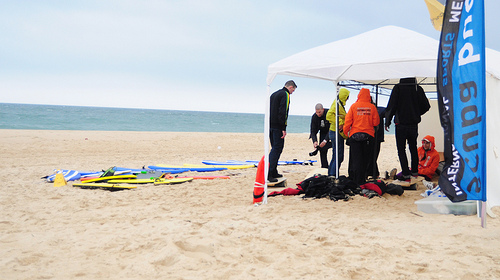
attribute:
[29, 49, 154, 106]
clouds — white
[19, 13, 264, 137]
sky — blue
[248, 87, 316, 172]
man —   in black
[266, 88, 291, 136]
shirt — black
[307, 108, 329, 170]
wetsuit — black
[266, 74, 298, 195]
wetsuit — black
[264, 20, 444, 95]
canopy — white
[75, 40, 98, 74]
clouds — white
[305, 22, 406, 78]
tent — white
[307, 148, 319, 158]
socks — black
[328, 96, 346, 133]
jacket — yellow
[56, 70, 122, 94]
clouds — white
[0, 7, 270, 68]
sky — blue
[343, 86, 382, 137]
hooded jacket — orange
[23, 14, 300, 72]
clouds — white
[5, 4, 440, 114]
sky — blue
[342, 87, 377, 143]
windbreaker — orange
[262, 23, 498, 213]
canopy — white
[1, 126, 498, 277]
beach — sandy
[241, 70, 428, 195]
people —  group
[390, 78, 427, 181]
clothing — black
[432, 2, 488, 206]
banner — blue and black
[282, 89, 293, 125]
lines — yellow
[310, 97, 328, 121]
hair — gray